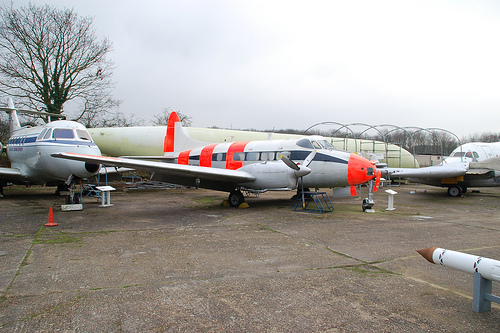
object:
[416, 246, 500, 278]
missile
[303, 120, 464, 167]
plane hangar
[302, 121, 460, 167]
frame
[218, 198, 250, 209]
blocks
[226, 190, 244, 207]
landing wheel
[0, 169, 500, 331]
ground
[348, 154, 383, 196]
nose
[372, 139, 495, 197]
airplane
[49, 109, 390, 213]
airplane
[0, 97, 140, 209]
airplane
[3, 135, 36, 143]
blue stripe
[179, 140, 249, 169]
orange stripes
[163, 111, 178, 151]
orange stripes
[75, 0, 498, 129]
sky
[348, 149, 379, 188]
paint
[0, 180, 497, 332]
pavement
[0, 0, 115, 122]
bare tree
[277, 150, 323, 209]
propeller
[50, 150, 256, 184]
wing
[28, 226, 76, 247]
grass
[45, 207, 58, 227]
cone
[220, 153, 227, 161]
window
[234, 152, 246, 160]
window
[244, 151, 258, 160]
window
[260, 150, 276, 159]
window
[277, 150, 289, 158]
window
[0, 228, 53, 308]
cracks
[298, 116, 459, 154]
object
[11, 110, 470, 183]
gate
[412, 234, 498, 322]
object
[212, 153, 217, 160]
windows